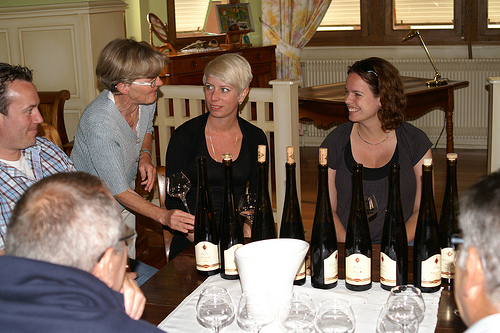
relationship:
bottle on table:
[190, 154, 218, 270] [155, 268, 195, 331]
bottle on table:
[214, 150, 243, 268] [155, 268, 195, 331]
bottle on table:
[252, 138, 275, 232] [155, 268, 195, 331]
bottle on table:
[281, 143, 306, 235] [155, 268, 195, 331]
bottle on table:
[313, 154, 338, 285] [155, 268, 195, 331]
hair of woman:
[348, 59, 406, 135] [306, 46, 475, 249]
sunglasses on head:
[346, 52, 383, 90] [306, 57, 446, 252]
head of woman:
[306, 57, 446, 252] [296, 45, 451, 260]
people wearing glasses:
[69, 36, 195, 262] [126, 72, 168, 95]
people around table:
[56, 40, 420, 202] [146, 231, 353, 321]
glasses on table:
[191, 283, 430, 331] [140, 248, 491, 330]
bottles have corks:
[244, 164, 389, 289] [242, 135, 327, 163]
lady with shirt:
[165, 54, 270, 256] [166, 114, 273, 232]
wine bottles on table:
[181, 140, 481, 296] [150, 236, 470, 325]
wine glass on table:
[188, 282, 230, 332] [134, 238, 474, 330]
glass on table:
[233, 293, 281, 333] [134, 238, 474, 330]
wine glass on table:
[279, 291, 315, 331] [134, 238, 474, 330]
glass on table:
[311, 299, 358, 333] [134, 238, 474, 330]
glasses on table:
[387, 283, 429, 333] [134, 238, 474, 330]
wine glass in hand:
[168, 177, 198, 211] [175, 203, 192, 233]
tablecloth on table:
[157, 271, 444, 330] [140, 248, 491, 330]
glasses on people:
[120, 74, 160, 87] [69, 36, 195, 262]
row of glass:
[196, 278, 433, 329] [376, 300, 423, 332]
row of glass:
[196, 278, 433, 329] [311, 296, 358, 331]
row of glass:
[196, 278, 433, 329] [196, 282, 233, 328]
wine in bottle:
[184, 142, 223, 284] [250, 134, 272, 252]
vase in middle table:
[235, 234, 307, 329] [160, 232, 407, 332]